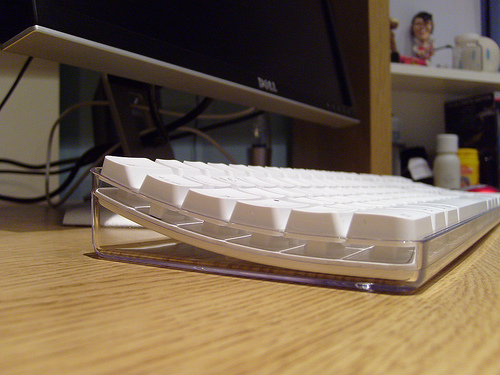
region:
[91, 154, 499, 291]
white and clear computer keyboard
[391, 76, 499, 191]
shelf with plastic bottles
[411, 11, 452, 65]
Elvis bobble head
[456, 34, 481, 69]
clear plastic pill bottle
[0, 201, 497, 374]
light wood grain tabletop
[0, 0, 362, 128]
Dell computer monitor with silver frame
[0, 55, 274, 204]
computer cords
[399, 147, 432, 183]
dark plastic bottle with white label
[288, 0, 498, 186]
shelf unit with white interior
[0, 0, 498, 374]
desktop computer on tabletop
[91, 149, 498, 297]
white keyboard on desk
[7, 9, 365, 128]
Dell brand monitor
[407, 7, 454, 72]
Elvis bobble head on shelf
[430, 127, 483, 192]
white and yellow containers on shelf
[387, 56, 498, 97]
white shelf in background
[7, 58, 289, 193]
data and power cables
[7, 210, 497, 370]
wood desk surface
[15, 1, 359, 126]
monitor with blank screen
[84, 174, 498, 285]
clear keyboard body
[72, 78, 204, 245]
grey monitor stand under monitor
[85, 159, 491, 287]
key board on a desk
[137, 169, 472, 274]
white keyboardon a desk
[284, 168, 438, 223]
white keys on keyboard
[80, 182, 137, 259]
see through bottom of keyboard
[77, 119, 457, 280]
curved keyboard on desk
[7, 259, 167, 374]
brown wooden desk below key board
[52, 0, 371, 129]
black computer monitor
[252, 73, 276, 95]
logo on bottom of monitor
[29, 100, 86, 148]
grey wire behind computer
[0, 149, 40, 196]
black wires behind computer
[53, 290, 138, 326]
this is a table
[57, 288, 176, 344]
the table is wooden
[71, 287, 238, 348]
the table is brown in color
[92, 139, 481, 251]
this is a keyboard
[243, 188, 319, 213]
these are the buttons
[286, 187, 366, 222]
the buttons are white in color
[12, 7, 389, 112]
this is a monitor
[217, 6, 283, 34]
the monitor is off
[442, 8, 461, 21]
this is the wall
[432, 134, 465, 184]
this is a bottle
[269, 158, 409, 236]
this is a key board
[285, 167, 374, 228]
the key board is white in color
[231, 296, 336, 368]
this is the table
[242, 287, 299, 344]
the table is brown in color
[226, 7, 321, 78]
this is the screen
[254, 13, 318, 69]
the screen is off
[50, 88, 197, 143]
these are the cables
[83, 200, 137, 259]
this is a stand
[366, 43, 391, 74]
this is a board